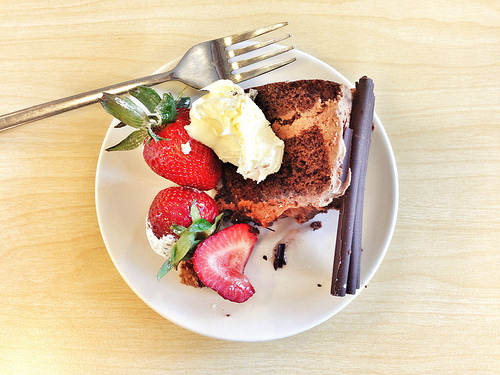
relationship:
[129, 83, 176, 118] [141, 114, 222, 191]
leaf on strawberry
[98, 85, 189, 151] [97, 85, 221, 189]
leaf is on strawberry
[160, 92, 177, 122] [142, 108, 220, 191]
leaf is on strawberry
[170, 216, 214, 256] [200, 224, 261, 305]
green leaf is on strawberry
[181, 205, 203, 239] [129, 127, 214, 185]
green leaf is on strawberry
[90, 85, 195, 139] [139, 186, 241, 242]
green leaf is on strawberry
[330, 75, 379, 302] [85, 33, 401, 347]
stick on plate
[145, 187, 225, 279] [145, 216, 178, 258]
strawberry in middle with chantilly cream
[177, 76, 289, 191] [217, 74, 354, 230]
cream on top cake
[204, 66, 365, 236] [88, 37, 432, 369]
cake on plate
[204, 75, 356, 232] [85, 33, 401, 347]
cake on plate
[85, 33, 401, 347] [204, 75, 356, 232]
plate of cake